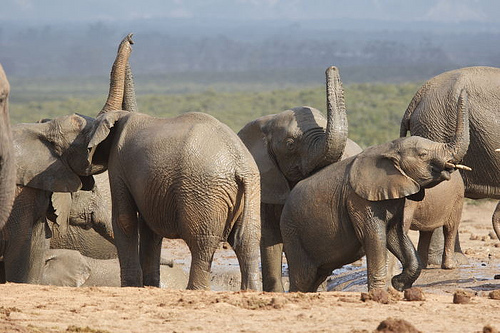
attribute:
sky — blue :
[0, 3, 498, 65]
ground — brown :
[0, 195, 497, 332]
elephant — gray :
[231, 72, 359, 289]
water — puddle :
[340, 267, 362, 288]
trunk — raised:
[310, 59, 350, 174]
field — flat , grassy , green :
[0, 83, 498, 329]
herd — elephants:
[0, 31, 498, 304]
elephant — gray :
[393, 65, 498, 246]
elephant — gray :
[77, 82, 269, 295]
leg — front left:
[99, 227, 159, 282]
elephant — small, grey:
[277, 88, 471, 293]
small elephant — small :
[283, 86, 475, 302]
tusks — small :
[443, 162, 472, 176]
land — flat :
[0, 90, 498, 330]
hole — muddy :
[104, 245, 386, 308]